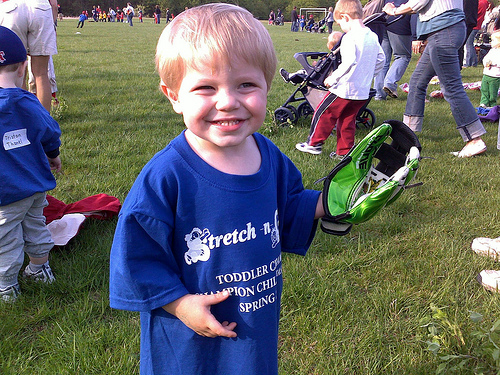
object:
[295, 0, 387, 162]
stroller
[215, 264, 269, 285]
lettering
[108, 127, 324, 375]
shirt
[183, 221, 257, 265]
letters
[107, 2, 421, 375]
boy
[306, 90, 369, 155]
jogging pants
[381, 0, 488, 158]
woman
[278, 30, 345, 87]
stroller